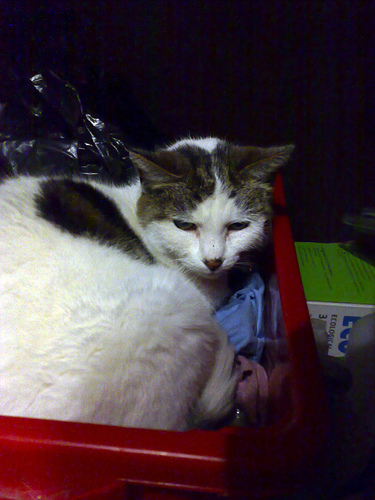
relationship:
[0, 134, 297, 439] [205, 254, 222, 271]
cat has nose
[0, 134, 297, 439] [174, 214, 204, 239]
cat has eye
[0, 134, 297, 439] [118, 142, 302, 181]
cat has ears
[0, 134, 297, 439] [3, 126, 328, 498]
cat in a box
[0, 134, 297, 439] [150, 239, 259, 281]
cat has whiskers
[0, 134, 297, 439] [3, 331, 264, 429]
cat has tail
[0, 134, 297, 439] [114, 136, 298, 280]
cat has head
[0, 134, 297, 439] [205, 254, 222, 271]
cat has a nose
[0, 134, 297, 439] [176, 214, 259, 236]
cat has eyes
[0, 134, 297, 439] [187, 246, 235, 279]
cat has mouth